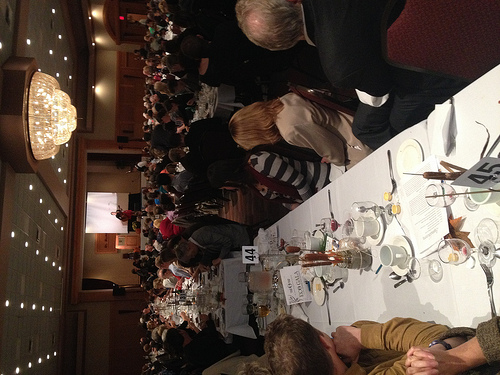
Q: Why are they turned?
A: To see the speaker.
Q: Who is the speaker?
A: A woman.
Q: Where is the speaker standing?
A: In the front of the room.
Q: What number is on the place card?
A: Forty-four.